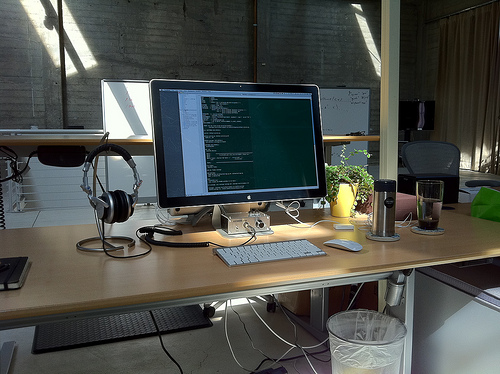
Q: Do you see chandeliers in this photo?
A: No, there are no chandeliers.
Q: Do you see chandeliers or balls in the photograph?
A: No, there are no chandeliers or balls.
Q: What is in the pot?
A: The plant is in the pot.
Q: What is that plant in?
A: The plant is in the pot.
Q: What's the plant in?
A: The plant is in the pot.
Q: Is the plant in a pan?
A: No, the plant is in a pot.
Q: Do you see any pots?
A: Yes, there is a pot.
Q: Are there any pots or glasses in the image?
A: Yes, there is a pot.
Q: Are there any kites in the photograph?
A: No, there are no kites.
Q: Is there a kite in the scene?
A: No, there are no kites.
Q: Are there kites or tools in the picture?
A: No, there are no kites or tools.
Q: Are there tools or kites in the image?
A: No, there are no kites or tools.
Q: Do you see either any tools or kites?
A: No, there are no kites or tools.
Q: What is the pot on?
A: The pot is on the desk.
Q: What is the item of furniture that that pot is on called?
A: The piece of furniture is a desk.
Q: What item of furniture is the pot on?
A: The pot is on the desk.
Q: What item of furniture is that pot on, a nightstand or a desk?
A: The pot is on a desk.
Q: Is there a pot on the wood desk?
A: Yes, there is a pot on the desk.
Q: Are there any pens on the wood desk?
A: No, there is a pot on the desk.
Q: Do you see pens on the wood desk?
A: No, there is a pot on the desk.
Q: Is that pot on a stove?
A: No, the pot is on the desk.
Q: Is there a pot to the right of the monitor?
A: Yes, there is a pot to the right of the monitor.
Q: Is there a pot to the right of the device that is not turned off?
A: Yes, there is a pot to the right of the monitor.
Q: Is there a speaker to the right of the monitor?
A: No, there is a pot to the right of the monitor.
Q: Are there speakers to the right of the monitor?
A: No, there is a pot to the right of the monitor.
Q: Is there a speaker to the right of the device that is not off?
A: No, there is a pot to the right of the monitor.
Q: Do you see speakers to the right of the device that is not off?
A: No, there is a pot to the right of the monitor.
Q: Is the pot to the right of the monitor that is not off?
A: Yes, the pot is to the right of the monitor.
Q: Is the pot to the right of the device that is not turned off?
A: Yes, the pot is to the right of the monitor.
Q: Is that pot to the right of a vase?
A: No, the pot is to the right of the monitor.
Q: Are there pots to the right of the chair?
A: No, the pot is to the left of the chair.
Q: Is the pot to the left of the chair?
A: Yes, the pot is to the left of the chair.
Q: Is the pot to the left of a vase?
A: No, the pot is to the left of the chair.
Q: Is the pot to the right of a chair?
A: No, the pot is to the left of a chair.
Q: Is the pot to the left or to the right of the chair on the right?
A: The pot is to the left of the chair.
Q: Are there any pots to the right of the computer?
A: Yes, there is a pot to the right of the computer.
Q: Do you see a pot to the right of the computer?
A: Yes, there is a pot to the right of the computer.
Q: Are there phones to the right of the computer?
A: No, there is a pot to the right of the computer.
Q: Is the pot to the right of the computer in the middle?
A: Yes, the pot is to the right of the computer.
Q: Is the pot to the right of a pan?
A: No, the pot is to the right of the computer.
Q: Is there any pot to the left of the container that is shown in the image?
A: Yes, there is a pot to the left of the container.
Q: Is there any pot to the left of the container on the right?
A: Yes, there is a pot to the left of the container.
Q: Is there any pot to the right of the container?
A: No, the pot is to the left of the container.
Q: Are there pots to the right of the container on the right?
A: No, the pot is to the left of the container.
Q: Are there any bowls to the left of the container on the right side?
A: No, there is a pot to the left of the container.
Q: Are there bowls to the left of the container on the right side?
A: No, there is a pot to the left of the container.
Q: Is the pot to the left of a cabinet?
A: No, the pot is to the left of the container.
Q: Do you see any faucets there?
A: No, there are no faucets.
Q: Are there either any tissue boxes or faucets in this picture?
A: No, there are no faucets or tissue boxes.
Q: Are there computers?
A: Yes, there is a computer.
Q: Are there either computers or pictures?
A: Yes, there is a computer.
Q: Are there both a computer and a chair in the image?
A: Yes, there are both a computer and a chair.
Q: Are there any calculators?
A: No, there are no calculators.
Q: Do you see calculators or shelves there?
A: No, there are no calculators or shelves.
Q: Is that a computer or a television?
A: That is a computer.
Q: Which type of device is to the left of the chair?
A: The device is a computer.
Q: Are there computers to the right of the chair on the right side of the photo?
A: No, the computer is to the left of the chair.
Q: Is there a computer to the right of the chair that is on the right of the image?
A: No, the computer is to the left of the chair.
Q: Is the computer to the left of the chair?
A: Yes, the computer is to the left of the chair.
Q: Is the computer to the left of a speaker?
A: No, the computer is to the left of the chair.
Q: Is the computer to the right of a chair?
A: No, the computer is to the left of a chair.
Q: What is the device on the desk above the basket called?
A: The device is a computer.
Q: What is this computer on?
A: The computer is on the desk.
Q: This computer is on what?
A: The computer is on the desk.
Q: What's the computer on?
A: The computer is on the desk.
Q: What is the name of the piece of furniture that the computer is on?
A: The piece of furniture is a desk.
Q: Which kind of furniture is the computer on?
A: The computer is on the desk.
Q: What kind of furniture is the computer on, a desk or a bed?
A: The computer is on a desk.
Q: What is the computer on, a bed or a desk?
A: The computer is on a desk.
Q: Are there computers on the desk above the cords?
A: Yes, there is a computer on the desk.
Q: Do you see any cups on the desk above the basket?
A: No, there is a computer on the desk.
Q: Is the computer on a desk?
A: Yes, the computer is on a desk.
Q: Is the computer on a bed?
A: No, the computer is on a desk.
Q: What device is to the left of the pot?
A: The device is a computer.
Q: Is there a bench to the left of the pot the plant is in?
A: No, there is a computer to the left of the pot.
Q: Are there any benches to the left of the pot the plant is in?
A: No, there is a computer to the left of the pot.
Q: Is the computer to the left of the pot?
A: Yes, the computer is to the left of the pot.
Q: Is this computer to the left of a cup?
A: No, the computer is to the left of the pot.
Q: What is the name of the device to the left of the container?
A: The device is a computer.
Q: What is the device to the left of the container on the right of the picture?
A: The device is a computer.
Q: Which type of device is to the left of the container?
A: The device is a computer.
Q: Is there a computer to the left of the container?
A: Yes, there is a computer to the left of the container.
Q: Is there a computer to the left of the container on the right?
A: Yes, there is a computer to the left of the container.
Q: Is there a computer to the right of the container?
A: No, the computer is to the left of the container.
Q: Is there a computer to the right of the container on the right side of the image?
A: No, the computer is to the left of the container.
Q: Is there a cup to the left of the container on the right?
A: No, there is a computer to the left of the container.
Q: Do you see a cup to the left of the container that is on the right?
A: No, there is a computer to the left of the container.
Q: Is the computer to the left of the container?
A: Yes, the computer is to the left of the container.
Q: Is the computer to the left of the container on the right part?
A: Yes, the computer is to the left of the container.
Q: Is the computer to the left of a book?
A: No, the computer is to the left of the container.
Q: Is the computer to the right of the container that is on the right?
A: No, the computer is to the left of the container.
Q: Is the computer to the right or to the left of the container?
A: The computer is to the left of the container.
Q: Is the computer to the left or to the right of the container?
A: The computer is to the left of the container.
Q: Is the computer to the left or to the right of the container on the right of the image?
A: The computer is to the left of the container.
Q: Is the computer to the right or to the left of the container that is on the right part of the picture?
A: The computer is to the left of the container.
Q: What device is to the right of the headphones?
A: The device is a computer.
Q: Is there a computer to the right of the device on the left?
A: Yes, there is a computer to the right of the headphones.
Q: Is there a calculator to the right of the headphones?
A: No, there is a computer to the right of the headphones.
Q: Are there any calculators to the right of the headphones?
A: No, there is a computer to the right of the headphones.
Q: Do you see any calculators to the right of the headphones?
A: No, there is a computer to the right of the headphones.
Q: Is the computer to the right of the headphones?
A: Yes, the computer is to the right of the headphones.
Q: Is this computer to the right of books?
A: No, the computer is to the right of the headphones.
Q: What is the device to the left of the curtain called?
A: The device is a computer.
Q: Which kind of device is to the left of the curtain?
A: The device is a computer.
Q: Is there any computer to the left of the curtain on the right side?
A: Yes, there is a computer to the left of the curtain.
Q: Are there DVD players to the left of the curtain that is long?
A: No, there is a computer to the left of the curtain.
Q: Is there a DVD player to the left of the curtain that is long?
A: No, there is a computer to the left of the curtain.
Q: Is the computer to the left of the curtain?
A: Yes, the computer is to the left of the curtain.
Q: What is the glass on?
A: The glass is on the desk.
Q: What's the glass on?
A: The glass is on the desk.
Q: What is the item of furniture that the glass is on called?
A: The piece of furniture is a desk.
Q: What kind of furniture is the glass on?
A: The glass is on the desk.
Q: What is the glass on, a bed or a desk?
A: The glass is on a desk.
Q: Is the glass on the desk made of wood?
A: Yes, the glass is on the desk.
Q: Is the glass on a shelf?
A: No, the glass is on the desk.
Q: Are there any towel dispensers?
A: No, there are no towel dispensers.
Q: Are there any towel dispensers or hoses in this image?
A: No, there are no towel dispensers or hoses.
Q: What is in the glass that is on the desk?
A: The water is in the glass.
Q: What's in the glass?
A: The water is in the glass.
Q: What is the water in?
A: The water is in the glass.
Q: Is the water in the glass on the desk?
A: Yes, the water is in the glass.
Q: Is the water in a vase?
A: No, the water is in the glass.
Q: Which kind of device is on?
A: The device is a monitor.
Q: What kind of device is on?
A: The device is a monitor.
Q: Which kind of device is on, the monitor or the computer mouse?
A: The monitor is on.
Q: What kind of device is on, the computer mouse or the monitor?
A: The monitor is on.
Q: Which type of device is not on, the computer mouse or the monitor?
A: The computer mouse is not on.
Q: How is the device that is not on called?
A: The device is a computer mouse.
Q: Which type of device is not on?
A: The device is a computer mouse.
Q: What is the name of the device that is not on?
A: The device is a computer mouse.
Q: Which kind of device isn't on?
A: The device is a computer mouse.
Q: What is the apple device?
A: The device is a monitor.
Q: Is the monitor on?
A: Yes, the monitor is on.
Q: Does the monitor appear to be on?
A: Yes, the monitor is on.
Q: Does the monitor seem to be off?
A: No, the monitor is on.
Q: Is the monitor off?
A: No, the monitor is on.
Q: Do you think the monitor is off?
A: No, the monitor is on.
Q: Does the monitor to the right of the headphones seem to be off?
A: No, the monitor is on.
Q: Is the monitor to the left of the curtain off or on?
A: The monitor is on.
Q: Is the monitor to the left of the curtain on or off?
A: The monitor is on.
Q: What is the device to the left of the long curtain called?
A: The device is a monitor.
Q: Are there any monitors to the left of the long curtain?
A: Yes, there is a monitor to the left of the curtain.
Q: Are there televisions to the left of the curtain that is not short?
A: No, there is a monitor to the left of the curtain.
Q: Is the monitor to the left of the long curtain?
A: Yes, the monitor is to the left of the curtain.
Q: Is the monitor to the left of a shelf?
A: No, the monitor is to the left of the curtain.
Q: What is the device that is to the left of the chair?
A: The device is a monitor.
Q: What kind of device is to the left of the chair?
A: The device is a monitor.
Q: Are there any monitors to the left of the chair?
A: Yes, there is a monitor to the left of the chair.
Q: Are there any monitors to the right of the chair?
A: No, the monitor is to the left of the chair.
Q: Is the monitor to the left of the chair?
A: Yes, the monitor is to the left of the chair.